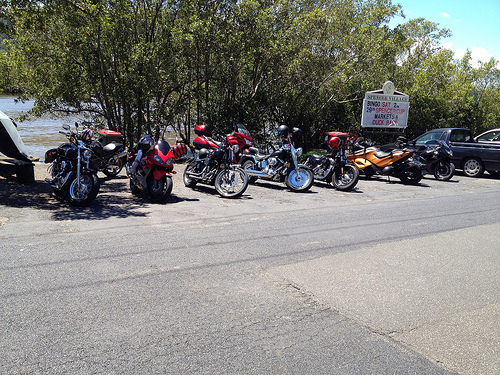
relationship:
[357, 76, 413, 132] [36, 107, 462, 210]
sign behind motorcycles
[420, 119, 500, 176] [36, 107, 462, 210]
truck next to motorcycles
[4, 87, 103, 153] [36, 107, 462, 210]
water behind parking lot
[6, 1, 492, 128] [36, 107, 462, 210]
trees behind motorcycles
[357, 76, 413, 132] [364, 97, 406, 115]
sing says bingo saturday at 2pm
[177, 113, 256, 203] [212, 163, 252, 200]
motorcycle has black tire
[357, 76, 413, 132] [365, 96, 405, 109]
sign has black letters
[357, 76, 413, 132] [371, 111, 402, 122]
sign has blue letters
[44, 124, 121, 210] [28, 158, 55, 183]
motorcycles has container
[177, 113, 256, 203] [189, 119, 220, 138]
bike has red container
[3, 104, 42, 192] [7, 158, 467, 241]
tent in parking lot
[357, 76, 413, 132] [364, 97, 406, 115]
sign says bingo sat 2pm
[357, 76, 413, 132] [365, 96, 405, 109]
sign says terrace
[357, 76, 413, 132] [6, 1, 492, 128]
sign next to trees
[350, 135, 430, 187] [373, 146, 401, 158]
motorcycle has black sit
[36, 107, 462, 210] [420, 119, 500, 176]
motorcycles next to black truck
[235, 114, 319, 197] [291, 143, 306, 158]
motorcycle with headlight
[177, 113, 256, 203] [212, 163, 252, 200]
motorcycle seen front tire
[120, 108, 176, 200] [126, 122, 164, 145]
motorcycle has bow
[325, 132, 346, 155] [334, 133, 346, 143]
helmet on handlebar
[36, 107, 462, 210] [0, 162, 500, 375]
motorcycles on pavement